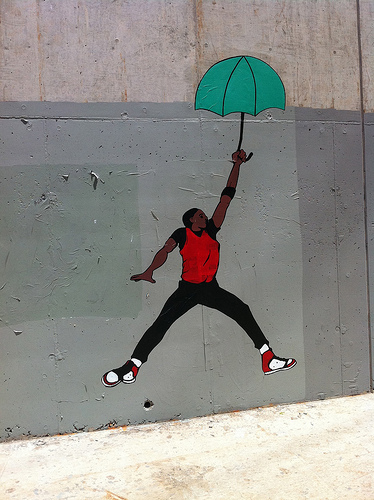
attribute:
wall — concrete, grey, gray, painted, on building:
[1, 1, 373, 444]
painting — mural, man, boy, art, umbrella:
[102, 54, 297, 387]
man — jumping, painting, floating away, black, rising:
[100, 148, 296, 388]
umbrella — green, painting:
[194, 56, 286, 163]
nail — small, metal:
[90, 169, 100, 182]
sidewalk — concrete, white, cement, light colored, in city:
[2, 392, 374, 500]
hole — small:
[142, 399, 154, 410]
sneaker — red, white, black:
[260, 347, 295, 375]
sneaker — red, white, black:
[100, 359, 139, 388]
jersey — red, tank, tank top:
[179, 227, 219, 285]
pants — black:
[131, 276, 271, 363]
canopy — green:
[192, 56, 286, 116]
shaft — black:
[236, 111, 252, 163]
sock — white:
[257, 343, 270, 355]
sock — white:
[129, 357, 143, 367]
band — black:
[220, 185, 236, 197]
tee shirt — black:
[170, 218, 221, 250]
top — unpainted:
[0, 1, 373, 109]